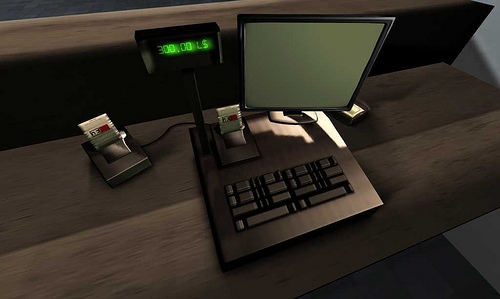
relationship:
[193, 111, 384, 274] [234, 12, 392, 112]
computers black moniter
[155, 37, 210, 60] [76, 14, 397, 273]
letters on register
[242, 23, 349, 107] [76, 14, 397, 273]
screen on register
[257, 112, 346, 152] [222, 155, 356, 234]
light near buttons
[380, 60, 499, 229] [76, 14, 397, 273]
counter under register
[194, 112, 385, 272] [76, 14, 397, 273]
base of register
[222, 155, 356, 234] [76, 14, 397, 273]
buttons on register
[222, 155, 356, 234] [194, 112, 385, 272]
buttons on base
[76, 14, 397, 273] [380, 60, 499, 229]
register on counter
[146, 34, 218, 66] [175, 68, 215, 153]
screen on pole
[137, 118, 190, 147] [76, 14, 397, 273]
cord on register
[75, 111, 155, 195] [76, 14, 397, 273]
timer near register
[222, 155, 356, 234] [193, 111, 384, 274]
buttons on computers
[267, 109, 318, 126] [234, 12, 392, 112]
stand for moniter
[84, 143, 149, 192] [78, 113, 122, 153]
box for calender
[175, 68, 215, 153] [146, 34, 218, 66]
pole holding screen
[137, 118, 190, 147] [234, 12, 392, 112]
cord for moniter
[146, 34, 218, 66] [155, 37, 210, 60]
screen for letters